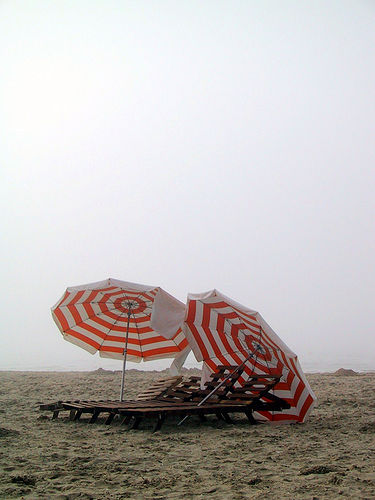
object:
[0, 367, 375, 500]
ground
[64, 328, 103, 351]
stripe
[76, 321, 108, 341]
stripe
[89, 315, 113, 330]
stripe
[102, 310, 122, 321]
stripe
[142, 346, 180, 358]
stripe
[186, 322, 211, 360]
stripe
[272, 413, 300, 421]
stripe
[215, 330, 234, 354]
stripe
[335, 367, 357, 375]
mound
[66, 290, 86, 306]
stripes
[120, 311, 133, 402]
pole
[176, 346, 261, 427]
pole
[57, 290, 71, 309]
stripes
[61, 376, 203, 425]
benches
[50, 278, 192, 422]
beach umbrella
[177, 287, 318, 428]
beach umbrella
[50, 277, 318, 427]
two umbrellas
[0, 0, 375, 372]
sky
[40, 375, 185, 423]
benches/umbrellas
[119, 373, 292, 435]
bench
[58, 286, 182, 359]
metal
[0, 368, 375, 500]
sand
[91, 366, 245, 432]
benches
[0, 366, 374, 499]
beach